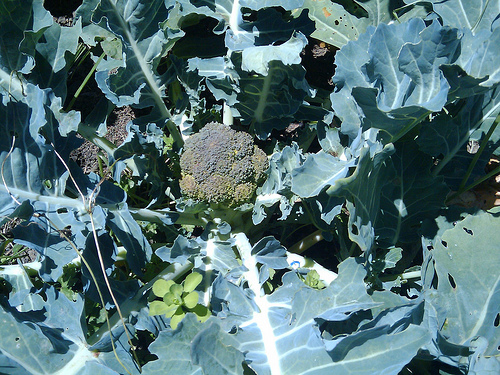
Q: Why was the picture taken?
A: To show the broccoli.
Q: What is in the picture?
A: Broccoli.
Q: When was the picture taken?
A: Summer.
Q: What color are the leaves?
A: Green.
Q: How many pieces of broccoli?
A: 1.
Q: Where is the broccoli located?
A: Garden.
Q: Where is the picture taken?
A: In a garden.